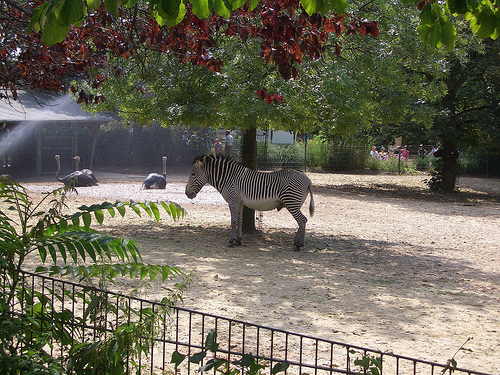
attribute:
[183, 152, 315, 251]
zebra — standing, black, white, alone, male, striped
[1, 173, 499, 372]
ground — dirt, sandy, brown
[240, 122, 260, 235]
tree — thin, tall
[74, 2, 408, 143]
leaves — green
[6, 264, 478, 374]
fence — metal, thin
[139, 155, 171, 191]
bird — laying, ostriche, alone, far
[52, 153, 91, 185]
bird — laying, ostriche, far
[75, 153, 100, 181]
bird — laying, ostriche, far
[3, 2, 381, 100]
leaves — red, brown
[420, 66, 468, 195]
tree — far, dark green, tall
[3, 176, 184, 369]
leaves — green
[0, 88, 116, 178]
building — far